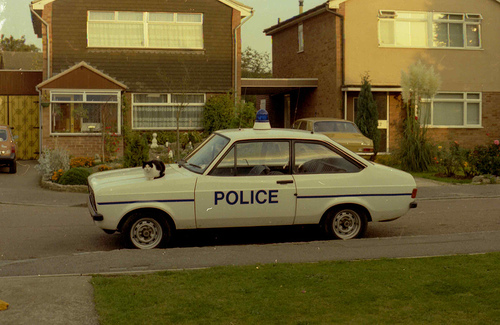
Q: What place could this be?
A: It is a street.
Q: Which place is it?
A: It is a street.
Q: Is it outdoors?
A: Yes, it is outdoors.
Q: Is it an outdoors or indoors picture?
A: It is outdoors.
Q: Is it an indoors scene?
A: No, it is outdoors.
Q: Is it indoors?
A: No, it is outdoors.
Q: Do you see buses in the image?
A: No, there are no buses.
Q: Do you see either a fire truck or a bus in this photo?
A: No, there are no buses or fire trucks.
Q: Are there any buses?
A: No, there are no buses.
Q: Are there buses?
A: No, there are no buses.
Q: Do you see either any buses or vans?
A: No, there are no buses or vans.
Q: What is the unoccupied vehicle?
A: The vehicle is a car.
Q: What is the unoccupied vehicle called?
A: The vehicle is a car.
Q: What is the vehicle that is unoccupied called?
A: The vehicle is a car.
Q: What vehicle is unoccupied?
A: The vehicle is a car.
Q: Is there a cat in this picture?
A: Yes, there is a cat.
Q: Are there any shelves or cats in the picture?
A: Yes, there is a cat.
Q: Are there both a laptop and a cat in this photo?
A: No, there is a cat but no laptops.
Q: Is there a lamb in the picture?
A: No, there are no lambs.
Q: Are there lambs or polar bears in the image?
A: No, there are no lambs or polar bears.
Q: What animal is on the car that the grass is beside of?
A: The cat is on the car.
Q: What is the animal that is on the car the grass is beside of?
A: The animal is a cat.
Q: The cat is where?
A: The cat is on the car.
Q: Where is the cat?
A: The cat is on the car.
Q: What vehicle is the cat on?
A: The cat is on the car.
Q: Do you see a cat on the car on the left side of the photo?
A: Yes, there is a cat on the car.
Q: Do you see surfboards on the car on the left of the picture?
A: No, there is a cat on the car.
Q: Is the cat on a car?
A: Yes, the cat is on a car.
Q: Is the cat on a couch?
A: No, the cat is on a car.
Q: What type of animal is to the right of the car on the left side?
A: The animal is a cat.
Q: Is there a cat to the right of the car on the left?
A: Yes, there is a cat to the right of the car.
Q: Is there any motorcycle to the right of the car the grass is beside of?
A: No, there is a cat to the right of the car.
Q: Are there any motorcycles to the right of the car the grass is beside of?
A: No, there is a cat to the right of the car.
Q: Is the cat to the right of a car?
A: Yes, the cat is to the right of a car.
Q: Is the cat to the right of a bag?
A: No, the cat is to the right of a car.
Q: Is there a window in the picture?
A: Yes, there are windows.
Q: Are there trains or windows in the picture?
A: Yes, there are windows.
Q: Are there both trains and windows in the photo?
A: No, there are windows but no trains.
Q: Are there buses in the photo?
A: No, there are no buses.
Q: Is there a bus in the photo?
A: No, there are no buses.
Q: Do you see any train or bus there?
A: No, there are no buses or trains.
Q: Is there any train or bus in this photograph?
A: No, there are no buses or trains.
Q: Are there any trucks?
A: No, there are no trucks.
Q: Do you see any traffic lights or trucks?
A: No, there are no trucks or traffic lights.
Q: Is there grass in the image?
A: Yes, there is grass.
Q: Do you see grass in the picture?
A: Yes, there is grass.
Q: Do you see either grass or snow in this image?
A: Yes, there is grass.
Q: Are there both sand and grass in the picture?
A: No, there is grass but no sand.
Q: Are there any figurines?
A: No, there are no figurines.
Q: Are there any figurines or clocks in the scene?
A: No, there are no figurines or clocks.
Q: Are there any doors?
A: Yes, there is a door.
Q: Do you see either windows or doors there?
A: Yes, there is a door.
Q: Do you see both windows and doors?
A: Yes, there are both a door and a window.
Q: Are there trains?
A: No, there are no trains.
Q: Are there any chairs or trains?
A: No, there are no trains or chairs.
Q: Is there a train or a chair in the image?
A: No, there are no trains or chairs.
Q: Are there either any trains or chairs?
A: No, there are no trains or chairs.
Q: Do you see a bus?
A: No, there are no buses.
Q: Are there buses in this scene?
A: No, there are no buses.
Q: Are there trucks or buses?
A: No, there are no buses or trucks.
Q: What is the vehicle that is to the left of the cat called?
A: The vehicle is a car.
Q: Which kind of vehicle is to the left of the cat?
A: The vehicle is a car.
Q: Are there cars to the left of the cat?
A: Yes, there is a car to the left of the cat.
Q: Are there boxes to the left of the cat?
A: No, there is a car to the left of the cat.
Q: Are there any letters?
A: Yes, there are letters.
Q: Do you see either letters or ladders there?
A: Yes, there are letters.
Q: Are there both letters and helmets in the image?
A: No, there are letters but no helmets.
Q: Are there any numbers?
A: No, there are no numbers.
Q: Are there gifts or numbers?
A: No, there are no numbers or gifts.